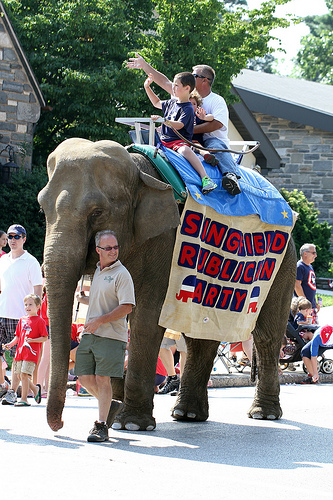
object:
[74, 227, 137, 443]
man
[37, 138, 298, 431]
elephant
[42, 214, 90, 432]
trunk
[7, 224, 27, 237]
blue hat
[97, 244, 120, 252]
glasses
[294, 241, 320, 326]
man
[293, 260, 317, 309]
blue shirt w/ star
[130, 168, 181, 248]
left ear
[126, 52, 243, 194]
three people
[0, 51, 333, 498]
event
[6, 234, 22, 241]
sunglasses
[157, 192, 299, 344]
banner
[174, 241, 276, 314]
republican party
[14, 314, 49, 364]
red shirt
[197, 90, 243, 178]
white shirt & jeans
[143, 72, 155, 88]
hand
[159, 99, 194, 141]
blue shirt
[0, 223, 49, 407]
man and boy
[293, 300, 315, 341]
kid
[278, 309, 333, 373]
stroller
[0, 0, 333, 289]
stone buildings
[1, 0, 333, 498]
background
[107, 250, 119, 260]
is smiling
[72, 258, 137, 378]
beige shirt & shorts